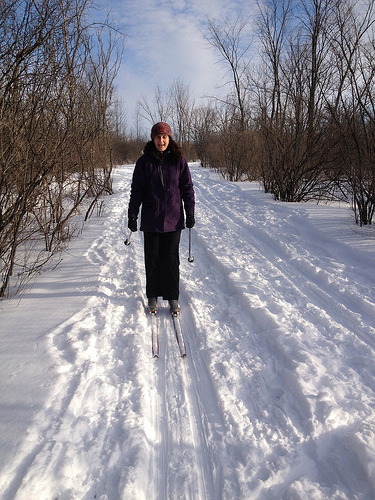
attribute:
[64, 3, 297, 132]
cloud — white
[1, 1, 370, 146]
sky — blue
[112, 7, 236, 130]
cloud — white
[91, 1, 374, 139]
clouds — white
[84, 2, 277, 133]
clouds — white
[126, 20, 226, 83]
clouds — white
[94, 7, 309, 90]
sky — blue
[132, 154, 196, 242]
jacket — purple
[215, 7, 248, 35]
clouds — white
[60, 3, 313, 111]
sky — blue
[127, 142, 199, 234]
coat — purple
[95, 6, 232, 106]
clouds — white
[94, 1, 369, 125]
sky — blue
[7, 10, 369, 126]
sky — partly cloudy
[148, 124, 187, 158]
woman — smiling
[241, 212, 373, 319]
snow — untouched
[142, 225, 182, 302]
pants — black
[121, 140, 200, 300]
outfit — black